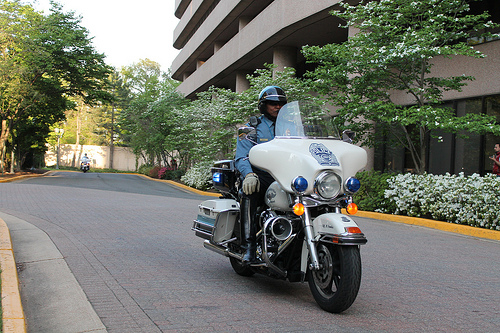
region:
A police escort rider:
[231, 84, 322, 196]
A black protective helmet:
[258, 84, 287, 105]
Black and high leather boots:
[240, 202, 254, 263]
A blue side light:
[292, 177, 307, 189]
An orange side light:
[291, 202, 302, 212]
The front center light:
[316, 170, 341, 199]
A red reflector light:
[345, 225, 360, 233]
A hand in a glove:
[242, 175, 259, 195]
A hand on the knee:
[240, 173, 258, 195]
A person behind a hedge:
[488, 142, 498, 175]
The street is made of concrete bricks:
[66, 205, 178, 330]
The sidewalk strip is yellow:
[369, 203, 491, 240]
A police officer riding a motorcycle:
[180, 64, 383, 314]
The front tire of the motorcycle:
[304, 228, 368, 313]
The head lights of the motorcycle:
[293, 170, 369, 200]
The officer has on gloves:
[241, 168, 263, 198]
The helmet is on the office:
[248, 83, 293, 120]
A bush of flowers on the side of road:
[388, 174, 499, 223]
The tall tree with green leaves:
[1, 8, 120, 186]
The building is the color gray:
[164, 3, 486, 103]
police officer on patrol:
[185, 84, 367, 314]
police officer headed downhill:
[192, 84, 368, 309]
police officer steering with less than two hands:
[190, 83, 370, 312]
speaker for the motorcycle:
[270, 217, 291, 241]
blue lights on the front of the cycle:
[292, 174, 362, 192]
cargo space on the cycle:
[190, 196, 238, 245]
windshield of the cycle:
[272, 100, 360, 139]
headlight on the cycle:
[317, 168, 342, 200]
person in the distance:
[77, 150, 92, 174]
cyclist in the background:
[75, 148, 91, 173]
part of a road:
[476, 222, 498, 229]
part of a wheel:
[351, 255, 355, 270]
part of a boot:
[246, 203, 251, 224]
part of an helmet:
[276, 94, 279, 105]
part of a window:
[461, 143, 467, 149]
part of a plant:
[382, 83, 398, 102]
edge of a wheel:
[343, 275, 350, 303]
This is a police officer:
[201, 95, 385, 329]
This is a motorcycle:
[201, 129, 416, 274]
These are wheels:
[295, 246, 396, 331]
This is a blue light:
[289, 180, 321, 200]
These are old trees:
[338, 56, 495, 177]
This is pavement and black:
[60, 202, 166, 327]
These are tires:
[323, 230, 381, 327]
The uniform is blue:
[217, 126, 253, 176]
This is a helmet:
[221, 91, 308, 144]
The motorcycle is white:
[259, 114, 376, 179]